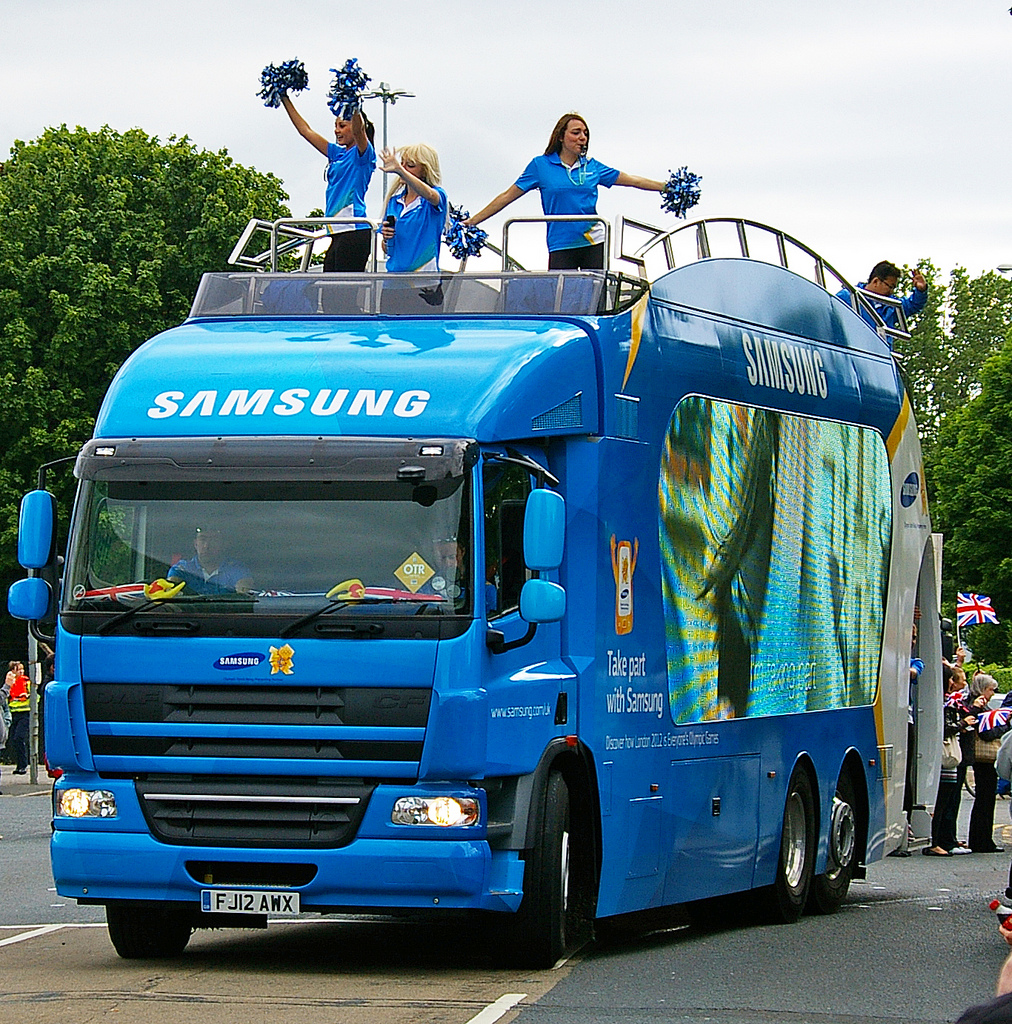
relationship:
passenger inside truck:
[163, 507, 260, 606] [91, 217, 930, 940]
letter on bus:
[683, 295, 835, 427] [467, 462, 790, 772]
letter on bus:
[146, 384, 182, 420] [8, 184, 937, 977]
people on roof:
[275, 75, 626, 247] [198, 263, 521, 309]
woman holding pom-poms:
[272, 82, 378, 275] [256, 57, 313, 106]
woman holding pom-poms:
[272, 82, 378, 275] [324, 55, 368, 123]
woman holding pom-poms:
[459, 110, 683, 266] [668, 165, 702, 225]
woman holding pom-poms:
[459, 110, 683, 266] [436, 195, 487, 270]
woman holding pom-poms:
[272, 82, 378, 275] [322, 49, 373, 122]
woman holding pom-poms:
[460, 110, 684, 266] [444, 193, 491, 259]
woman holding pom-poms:
[460, 110, 684, 266] [664, 156, 702, 220]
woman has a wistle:
[459, 110, 683, 266] [574, 139, 586, 161]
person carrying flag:
[957, 674, 1012, 845] [951, 701, 1006, 735]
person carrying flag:
[918, 662, 976, 858] [946, 585, 999, 680]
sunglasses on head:
[175, 518, 228, 536] [184, 504, 230, 564]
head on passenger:
[184, 504, 230, 564] [164, 507, 261, 606]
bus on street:
[8, 184, 937, 977] [697, 932, 1009, 1020]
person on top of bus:
[449, 104, 669, 271] [8, 184, 937, 977]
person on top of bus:
[379, 143, 454, 271] [8, 184, 937, 977]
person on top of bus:
[957, 674, 1012, 845] [8, 184, 937, 977]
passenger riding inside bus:
[163, 507, 260, 606] [8, 184, 937, 977]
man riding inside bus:
[405, 530, 502, 620] [8, 184, 937, 977]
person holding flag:
[957, 674, 1012, 845] [955, 701, 1010, 734]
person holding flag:
[933, 636, 977, 860] [950, 585, 1001, 634]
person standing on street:
[957, 674, 1012, 845] [0, 758, 1008, 1019]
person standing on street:
[933, 636, 977, 860] [0, 758, 1008, 1019]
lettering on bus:
[142, 382, 438, 415] [8, 184, 937, 977]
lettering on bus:
[736, 327, 844, 398] [8, 184, 937, 977]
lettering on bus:
[598, 642, 656, 686] [8, 184, 937, 977]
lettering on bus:
[602, 690, 675, 717] [8, 184, 937, 977]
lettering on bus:
[591, 714, 730, 758] [8, 184, 937, 977]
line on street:
[460, 942, 585, 1019] [0, 758, 1008, 1019]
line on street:
[0, 914, 111, 931] [0, 758, 1008, 1019]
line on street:
[258, 910, 357, 926] [0, 758, 1008, 1019]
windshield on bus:
[70, 471, 476, 640] [8, 184, 937, 977]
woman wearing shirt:
[459, 110, 683, 266] [521, 149, 624, 248]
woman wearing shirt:
[363, 139, 455, 280] [372, 184, 452, 270]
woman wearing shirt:
[272, 82, 378, 275] [311, 139, 373, 231]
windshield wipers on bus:
[274, 587, 448, 640] [8, 184, 937, 977]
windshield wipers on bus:
[85, 585, 267, 631] [8, 184, 937, 977]